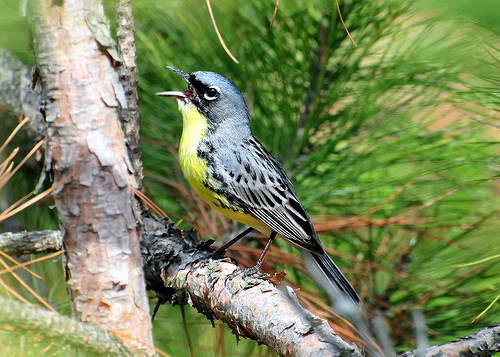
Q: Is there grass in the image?
A: Yes, there is grass.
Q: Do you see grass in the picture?
A: Yes, there is grass.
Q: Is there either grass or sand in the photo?
A: Yes, there is grass.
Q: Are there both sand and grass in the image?
A: No, there is grass but no sand.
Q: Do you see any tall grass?
A: Yes, there is tall grass.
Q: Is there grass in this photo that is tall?
A: Yes, there is grass that is tall.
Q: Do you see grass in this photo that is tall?
A: Yes, there is grass that is tall.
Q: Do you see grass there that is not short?
A: Yes, there is tall grass.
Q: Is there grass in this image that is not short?
A: Yes, there is tall grass.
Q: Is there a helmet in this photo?
A: No, there are no helmets.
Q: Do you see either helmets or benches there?
A: No, there are no helmets or benches.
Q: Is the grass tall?
A: Yes, the grass is tall.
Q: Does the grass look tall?
A: Yes, the grass is tall.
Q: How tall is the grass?
A: The grass is tall.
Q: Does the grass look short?
A: No, the grass is tall.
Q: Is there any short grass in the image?
A: No, there is grass but it is tall.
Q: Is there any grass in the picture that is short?
A: No, there is grass but it is tall.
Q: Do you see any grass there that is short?
A: No, there is grass but it is tall.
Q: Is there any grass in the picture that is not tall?
A: No, there is grass but it is tall.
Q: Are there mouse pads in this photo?
A: No, there are no mouse pads.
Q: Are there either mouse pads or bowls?
A: No, there are no mouse pads or bowls.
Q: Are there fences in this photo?
A: No, there are no fences.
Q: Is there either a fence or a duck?
A: No, there are no fences or ducks.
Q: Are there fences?
A: No, there are no fences.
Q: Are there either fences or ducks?
A: No, there are no fences or ducks.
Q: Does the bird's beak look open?
A: Yes, the beak is open.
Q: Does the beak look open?
A: Yes, the beak is open.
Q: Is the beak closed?
A: No, the beak is open.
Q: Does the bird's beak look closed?
A: No, the beak is open.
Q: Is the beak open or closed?
A: The beak is open.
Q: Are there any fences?
A: No, there are no fences.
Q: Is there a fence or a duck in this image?
A: No, there are no fences or ducks.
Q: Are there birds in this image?
A: Yes, there is a bird.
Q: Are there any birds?
A: Yes, there is a bird.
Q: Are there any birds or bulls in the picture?
A: Yes, there is a bird.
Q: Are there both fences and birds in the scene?
A: No, there is a bird but no fences.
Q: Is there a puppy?
A: No, there are no puppies.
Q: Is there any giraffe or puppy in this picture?
A: No, there are no puppies or giraffes.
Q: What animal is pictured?
A: The animal is a bird.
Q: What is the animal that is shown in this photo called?
A: The animal is a bird.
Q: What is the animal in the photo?
A: The animal is a bird.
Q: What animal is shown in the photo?
A: The animal is a bird.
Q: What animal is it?
A: The animal is a bird.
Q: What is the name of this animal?
A: This is a bird.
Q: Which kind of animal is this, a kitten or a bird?
A: This is a bird.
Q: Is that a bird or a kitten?
A: That is a bird.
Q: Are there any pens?
A: No, there are no pens.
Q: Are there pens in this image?
A: No, there are no pens.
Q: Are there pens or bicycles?
A: No, there are no pens or bicycles.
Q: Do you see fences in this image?
A: No, there are no fences.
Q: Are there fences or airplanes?
A: No, there are no fences or airplanes.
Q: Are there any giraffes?
A: No, there are no giraffes.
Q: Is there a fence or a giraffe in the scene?
A: No, there are no giraffes or fences.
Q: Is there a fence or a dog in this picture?
A: No, there are no fences or dogs.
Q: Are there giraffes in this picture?
A: No, there are no giraffes.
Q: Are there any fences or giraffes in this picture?
A: No, there are no giraffes or fences.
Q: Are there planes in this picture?
A: No, there are no planes.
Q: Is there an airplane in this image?
A: No, there are no airplanes.